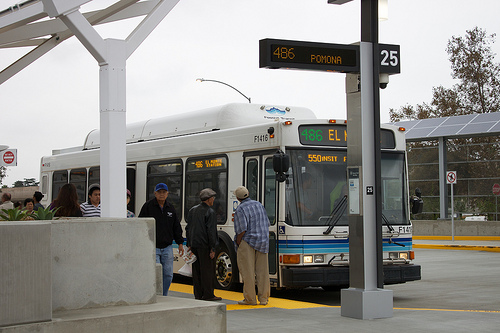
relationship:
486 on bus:
[269, 39, 290, 63] [30, 137, 346, 278]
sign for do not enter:
[442, 165, 458, 186] [447, 173, 457, 182]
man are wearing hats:
[232, 183, 271, 306] [197, 184, 259, 199]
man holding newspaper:
[223, 183, 270, 296] [170, 243, 192, 274]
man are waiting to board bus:
[232, 183, 271, 306] [30, 137, 346, 278]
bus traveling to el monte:
[30, 137, 346, 278] [319, 122, 347, 146]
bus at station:
[30, 137, 346, 278] [0, 24, 139, 300]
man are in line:
[232, 183, 271, 306] [179, 283, 257, 310]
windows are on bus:
[61, 157, 220, 219] [30, 137, 346, 278]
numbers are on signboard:
[380, 50, 397, 65] [379, 42, 400, 67]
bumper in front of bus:
[290, 264, 361, 288] [30, 137, 346, 278]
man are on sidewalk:
[232, 183, 271, 306] [235, 305, 297, 324]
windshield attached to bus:
[285, 149, 419, 229] [30, 137, 346, 278]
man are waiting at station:
[232, 183, 271, 306] [0, 24, 139, 300]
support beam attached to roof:
[84, 18, 128, 215] [18, 14, 122, 60]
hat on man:
[143, 181, 168, 193] [223, 183, 270, 296]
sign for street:
[442, 165, 458, 186] [447, 262, 475, 287]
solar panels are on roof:
[433, 115, 468, 140] [18, 14, 122, 60]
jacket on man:
[147, 210, 177, 249] [223, 183, 270, 296]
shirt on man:
[231, 203, 270, 243] [223, 183, 270, 296]